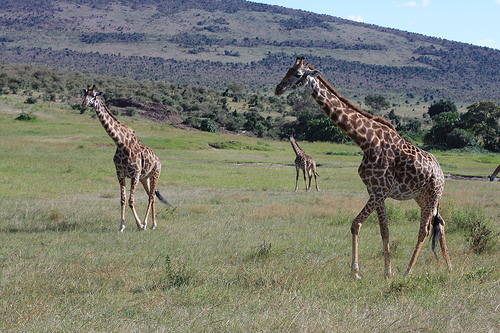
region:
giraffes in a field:
[10, 12, 488, 330]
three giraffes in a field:
[75, 60, 451, 268]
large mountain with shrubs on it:
[0, 0, 490, 145]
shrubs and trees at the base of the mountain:
[0, 63, 495, 144]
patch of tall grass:
[160, 250, 196, 290]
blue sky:
[270, 0, 490, 40]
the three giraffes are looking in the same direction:
[70, 70, 450, 280]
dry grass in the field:
[7, 186, 488, 317]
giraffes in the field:
[57, 46, 492, 310]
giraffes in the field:
[40, 22, 488, 309]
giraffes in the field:
[51, 19, 465, 292]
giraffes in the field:
[35, 23, 490, 326]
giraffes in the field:
[36, 36, 480, 294]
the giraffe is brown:
[65, 78, 184, 259]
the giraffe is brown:
[57, 63, 188, 245]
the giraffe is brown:
[52, 61, 192, 248]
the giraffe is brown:
[62, 67, 212, 302]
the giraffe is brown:
[52, 76, 177, 270]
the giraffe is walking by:
[275, 54, 457, 290]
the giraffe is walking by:
[77, 85, 169, 235]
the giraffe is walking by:
[283, 133, 320, 192]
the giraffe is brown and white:
[279, 60, 454, 291]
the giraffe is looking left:
[277, 58, 457, 284]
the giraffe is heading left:
[80, 86, 168, 231]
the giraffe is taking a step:
[275, 60, 452, 286]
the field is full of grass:
[5, 93, 495, 330]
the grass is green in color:
[2, 78, 499, 331]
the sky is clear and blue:
[242, 0, 494, 54]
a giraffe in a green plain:
[80, 80, 173, 235]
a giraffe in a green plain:
[285, 51, 466, 277]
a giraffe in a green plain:
[282, 133, 323, 194]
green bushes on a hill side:
[183, 112, 218, 134]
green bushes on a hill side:
[113, 87, 146, 99]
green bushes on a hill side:
[421, 103, 473, 155]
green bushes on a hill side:
[208, 56, 250, 71]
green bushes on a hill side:
[83, 30, 153, 43]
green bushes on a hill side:
[28, 50, 82, 68]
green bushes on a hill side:
[201, 18, 231, 28]